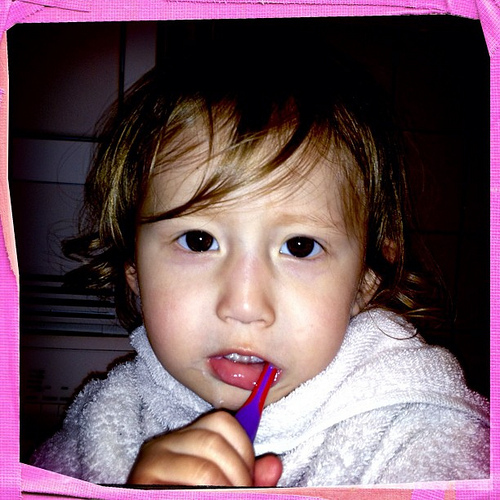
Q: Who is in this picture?
A: Child.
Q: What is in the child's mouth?
A: Toothbrush.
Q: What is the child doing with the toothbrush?
A: Brushing teeth.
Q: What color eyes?
A: Brown.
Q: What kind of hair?
A: Curly.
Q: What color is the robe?
A: White.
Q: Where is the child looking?
A: Camera.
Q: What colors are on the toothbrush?
A: Purple and pink.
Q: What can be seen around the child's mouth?
A: Toothpaste.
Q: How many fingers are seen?
A: 4.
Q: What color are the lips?
A: Red.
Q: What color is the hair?
A: Blonde.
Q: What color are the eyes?
A: Black.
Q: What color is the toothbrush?
A: Red and purple.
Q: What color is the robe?
A: White.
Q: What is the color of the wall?
A: White.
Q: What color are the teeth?
A: White.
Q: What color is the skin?
A: White.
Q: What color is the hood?
A: White.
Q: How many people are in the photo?
A: One.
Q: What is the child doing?
A: Brushing teeth.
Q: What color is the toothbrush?
A: Purple and pink.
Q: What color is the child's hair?
A: Brown.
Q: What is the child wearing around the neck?
A: Towel.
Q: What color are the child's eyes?
A: Dark brown.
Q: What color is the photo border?
A: Pink.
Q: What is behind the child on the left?
A: Vents.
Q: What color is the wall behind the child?
A: Tan and white.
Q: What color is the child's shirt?
A: White.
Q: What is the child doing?
A: Brushing teeth.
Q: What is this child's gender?
A: Female.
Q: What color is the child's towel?
A: White.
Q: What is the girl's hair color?
A: Blonde.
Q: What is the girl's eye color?
A: Brown.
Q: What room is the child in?
A: Bathroom.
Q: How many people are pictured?
A: One.